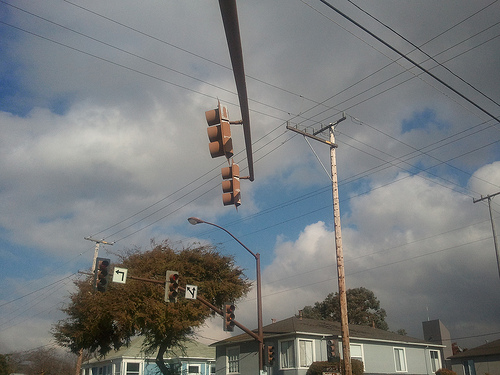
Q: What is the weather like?
A: It is cloudy.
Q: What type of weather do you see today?
A: It is cloudy.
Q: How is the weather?
A: It is cloudy.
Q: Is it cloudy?
A: Yes, it is cloudy.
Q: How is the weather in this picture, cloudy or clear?
A: It is cloudy.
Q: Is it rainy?
A: No, it is cloudy.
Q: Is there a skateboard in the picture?
A: No, there are no skateboards.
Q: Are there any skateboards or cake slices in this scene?
A: No, there are no skateboards or cake slices.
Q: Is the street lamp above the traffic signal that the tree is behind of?
A: Yes, the street lamp is above the traffic signal.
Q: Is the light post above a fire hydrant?
A: No, the light post is above the traffic signal.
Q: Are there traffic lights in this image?
A: Yes, there is a traffic light.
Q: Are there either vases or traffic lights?
A: Yes, there is a traffic light.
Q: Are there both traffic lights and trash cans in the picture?
A: No, there is a traffic light but no trash cans.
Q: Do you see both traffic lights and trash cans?
A: No, there is a traffic light but no trash cans.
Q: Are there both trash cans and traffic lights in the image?
A: No, there is a traffic light but no trash cans.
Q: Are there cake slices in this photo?
A: No, there are no cake slices.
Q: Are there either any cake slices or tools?
A: No, there are no cake slices or tools.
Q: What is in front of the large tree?
A: The traffic signal is in front of the tree.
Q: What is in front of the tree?
A: The traffic signal is in front of the tree.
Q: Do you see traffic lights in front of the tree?
A: Yes, there is a traffic light in front of the tree.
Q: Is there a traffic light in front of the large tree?
A: Yes, there is a traffic light in front of the tree.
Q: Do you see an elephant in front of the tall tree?
A: No, there is a traffic light in front of the tree.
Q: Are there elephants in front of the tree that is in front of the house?
A: No, there is a traffic light in front of the tree.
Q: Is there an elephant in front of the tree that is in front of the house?
A: No, there is a traffic light in front of the tree.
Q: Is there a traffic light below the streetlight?
A: Yes, there is a traffic light below the streetlight.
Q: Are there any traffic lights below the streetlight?
A: Yes, there is a traffic light below the streetlight.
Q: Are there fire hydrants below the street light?
A: No, there is a traffic light below the street light.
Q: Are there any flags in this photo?
A: No, there are no flags.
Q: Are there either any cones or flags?
A: No, there are no flags or cones.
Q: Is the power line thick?
A: Yes, the power line is thick.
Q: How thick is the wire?
A: The wire is thick.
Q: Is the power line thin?
A: No, the power line is thick.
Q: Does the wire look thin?
A: No, the wire is thick.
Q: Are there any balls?
A: No, there are no balls.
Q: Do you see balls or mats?
A: No, there are no balls or mats.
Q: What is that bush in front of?
A: The bush is in front of the house.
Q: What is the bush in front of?
A: The bush is in front of the house.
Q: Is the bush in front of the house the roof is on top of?
A: Yes, the bush is in front of the house.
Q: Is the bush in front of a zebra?
A: No, the bush is in front of the house.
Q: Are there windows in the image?
A: Yes, there is a window.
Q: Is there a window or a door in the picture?
A: Yes, there is a window.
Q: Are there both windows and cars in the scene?
A: No, there is a window but no cars.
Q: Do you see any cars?
A: No, there are no cars.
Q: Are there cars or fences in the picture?
A: No, there are no cars or fences.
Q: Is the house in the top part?
A: No, the house is in the bottom of the image.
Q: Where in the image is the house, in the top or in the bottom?
A: The house is in the bottom of the image.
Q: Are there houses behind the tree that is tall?
A: Yes, there is a house behind the tree.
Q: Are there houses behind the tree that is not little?
A: Yes, there is a house behind the tree.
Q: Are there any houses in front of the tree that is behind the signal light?
A: No, the house is behind the tree.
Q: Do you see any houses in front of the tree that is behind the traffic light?
A: No, the house is behind the tree.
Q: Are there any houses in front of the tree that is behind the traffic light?
A: No, the house is behind the tree.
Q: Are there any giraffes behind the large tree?
A: No, there is a house behind the tree.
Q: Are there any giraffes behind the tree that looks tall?
A: No, there is a house behind the tree.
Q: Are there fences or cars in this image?
A: No, there are no cars or fences.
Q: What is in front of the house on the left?
A: The tree is in front of the house.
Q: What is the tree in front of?
A: The tree is in front of the house.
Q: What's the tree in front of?
A: The tree is in front of the house.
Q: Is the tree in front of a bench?
A: No, the tree is in front of the house.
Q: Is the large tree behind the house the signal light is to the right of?
A: No, the tree is in front of the house.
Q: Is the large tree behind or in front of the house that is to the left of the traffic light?
A: The tree is in front of the house.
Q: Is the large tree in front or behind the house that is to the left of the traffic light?
A: The tree is in front of the house.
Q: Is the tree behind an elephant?
A: No, the tree is behind the signal light.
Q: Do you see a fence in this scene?
A: No, there are no fences.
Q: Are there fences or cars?
A: No, there are no fences or cars.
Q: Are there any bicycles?
A: No, there are no bicycles.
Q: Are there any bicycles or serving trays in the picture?
A: No, there are no bicycles or serving trays.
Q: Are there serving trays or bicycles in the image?
A: No, there are no bicycles or serving trays.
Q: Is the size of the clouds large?
A: Yes, the clouds are large.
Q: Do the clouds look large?
A: Yes, the clouds are large.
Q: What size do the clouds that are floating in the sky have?
A: The clouds have large size.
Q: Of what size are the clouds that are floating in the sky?
A: The clouds are large.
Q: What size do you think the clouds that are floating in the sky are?
A: The clouds are large.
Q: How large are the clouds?
A: The clouds are large.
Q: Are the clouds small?
A: No, the clouds are large.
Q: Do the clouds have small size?
A: No, the clouds are large.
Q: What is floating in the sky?
A: The clouds are floating in the sky.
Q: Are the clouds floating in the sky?
A: Yes, the clouds are floating in the sky.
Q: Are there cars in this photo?
A: No, there are no cars.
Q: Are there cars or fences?
A: No, there are no cars or fences.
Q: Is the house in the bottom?
A: Yes, the house is in the bottom of the image.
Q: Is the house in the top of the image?
A: No, the house is in the bottom of the image.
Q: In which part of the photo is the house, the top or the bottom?
A: The house is in the bottom of the image.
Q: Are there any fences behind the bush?
A: No, there is a house behind the bush.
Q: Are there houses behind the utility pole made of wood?
A: Yes, there is a house behind the telephone pole.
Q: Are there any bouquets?
A: No, there are no bouquets.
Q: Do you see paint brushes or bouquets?
A: No, there are no bouquets or paint brushes.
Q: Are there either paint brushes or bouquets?
A: No, there are no bouquets or paint brushes.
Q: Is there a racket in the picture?
A: No, there are no rackets.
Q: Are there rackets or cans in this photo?
A: No, there are no rackets or cans.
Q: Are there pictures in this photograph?
A: No, there are no pictures.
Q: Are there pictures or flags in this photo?
A: No, there are no pictures or flags.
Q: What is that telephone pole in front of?
A: The telephone pole is in front of the house.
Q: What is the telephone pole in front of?
A: The telephone pole is in front of the house.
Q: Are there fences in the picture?
A: No, there are no fences.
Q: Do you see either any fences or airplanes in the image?
A: No, there are no fences or airplanes.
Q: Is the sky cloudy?
A: Yes, the sky is cloudy.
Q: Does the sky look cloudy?
A: Yes, the sky is cloudy.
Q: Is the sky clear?
A: No, the sky is cloudy.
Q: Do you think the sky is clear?
A: No, the sky is cloudy.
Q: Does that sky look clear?
A: No, the sky is cloudy.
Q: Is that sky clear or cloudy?
A: The sky is cloudy.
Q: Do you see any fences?
A: No, there are no fences.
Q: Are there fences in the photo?
A: No, there are no fences.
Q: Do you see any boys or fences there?
A: No, there are no fences or boys.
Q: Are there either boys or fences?
A: No, there are no fences or boys.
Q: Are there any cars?
A: No, there are no cars.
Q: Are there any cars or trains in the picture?
A: No, there are no cars or trains.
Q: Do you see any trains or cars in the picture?
A: No, there are no cars or trains.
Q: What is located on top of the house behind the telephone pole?
A: The roof is on top of the house.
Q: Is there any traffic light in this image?
A: Yes, there is a traffic light.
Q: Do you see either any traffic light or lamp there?
A: Yes, there is a traffic light.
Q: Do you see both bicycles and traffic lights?
A: No, there is a traffic light but no bikes.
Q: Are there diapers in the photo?
A: No, there are no diapers.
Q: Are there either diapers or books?
A: No, there are no diapers or books.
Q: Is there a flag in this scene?
A: No, there are no flags.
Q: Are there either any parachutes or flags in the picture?
A: No, there are no flags or parachutes.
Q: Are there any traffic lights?
A: Yes, there is a traffic light.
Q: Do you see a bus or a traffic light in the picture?
A: Yes, there is a traffic light.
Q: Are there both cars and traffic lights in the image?
A: No, there is a traffic light but no cars.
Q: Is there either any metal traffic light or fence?
A: Yes, there is a metal traffic light.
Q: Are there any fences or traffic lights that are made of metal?
A: Yes, the traffic light is made of metal.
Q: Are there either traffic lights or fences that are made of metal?
A: Yes, the traffic light is made of metal.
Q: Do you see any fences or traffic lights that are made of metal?
A: Yes, the traffic light is made of metal.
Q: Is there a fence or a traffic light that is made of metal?
A: Yes, the traffic light is made of metal.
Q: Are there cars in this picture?
A: No, there are no cars.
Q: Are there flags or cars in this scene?
A: No, there are no cars or flags.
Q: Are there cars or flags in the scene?
A: No, there are no cars or flags.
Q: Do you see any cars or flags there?
A: No, there are no cars or flags.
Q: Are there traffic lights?
A: Yes, there is a traffic light.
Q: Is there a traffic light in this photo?
A: Yes, there is a traffic light.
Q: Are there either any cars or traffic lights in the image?
A: Yes, there is a traffic light.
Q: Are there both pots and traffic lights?
A: No, there is a traffic light but no pots.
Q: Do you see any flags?
A: No, there are no flags.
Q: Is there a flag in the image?
A: No, there are no flags.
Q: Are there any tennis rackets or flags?
A: No, there are no flags or tennis rackets.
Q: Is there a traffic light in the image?
A: Yes, there is a traffic light.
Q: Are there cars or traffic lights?
A: Yes, there is a traffic light.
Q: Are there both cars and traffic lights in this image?
A: No, there is a traffic light but no cars.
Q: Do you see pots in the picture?
A: No, there are no pots.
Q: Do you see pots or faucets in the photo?
A: No, there are no pots or faucets.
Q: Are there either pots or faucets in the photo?
A: No, there are no pots or faucets.